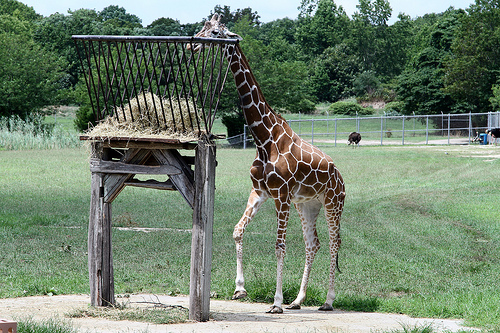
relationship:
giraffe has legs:
[185, 13, 346, 313] [231, 188, 352, 316]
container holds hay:
[68, 35, 239, 137] [83, 90, 209, 143]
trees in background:
[1, 2, 499, 135] [3, 2, 499, 161]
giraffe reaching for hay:
[185, 13, 346, 313] [83, 90, 209, 143]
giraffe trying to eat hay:
[185, 13, 346, 313] [83, 90, 209, 143]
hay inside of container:
[83, 90, 209, 143] [68, 35, 239, 137]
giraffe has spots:
[185, 13, 346, 313] [193, 23, 346, 288]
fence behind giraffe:
[218, 110, 499, 149] [185, 13, 346, 313]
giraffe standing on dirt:
[185, 13, 346, 313] [1, 292, 487, 332]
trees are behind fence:
[1, 2, 499, 135] [218, 110, 499, 149]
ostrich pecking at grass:
[345, 131, 361, 148] [4, 148, 495, 333]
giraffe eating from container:
[185, 13, 346, 313] [68, 35, 239, 137]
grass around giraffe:
[4, 148, 495, 333] [185, 13, 346, 313]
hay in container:
[83, 90, 209, 143] [68, 35, 239, 137]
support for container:
[78, 134, 218, 322] [68, 35, 239, 137]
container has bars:
[68, 35, 239, 137] [72, 39, 237, 135]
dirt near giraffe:
[1, 292, 487, 332] [185, 13, 346, 313]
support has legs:
[78, 134, 218, 322] [89, 141, 218, 322]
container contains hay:
[68, 35, 239, 137] [83, 90, 209, 143]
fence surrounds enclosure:
[218, 110, 499, 149] [0, 108, 496, 333]